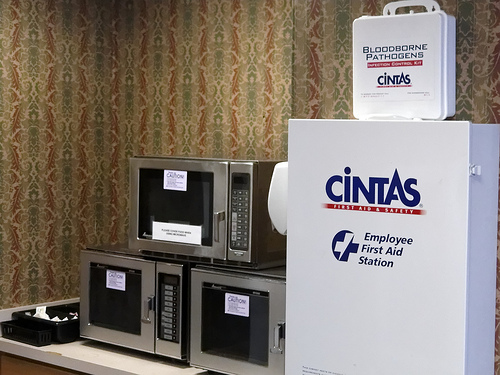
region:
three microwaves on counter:
[73, 150, 291, 373]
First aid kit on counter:
[290, 114, 490, 373]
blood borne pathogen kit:
[343, 3, 459, 119]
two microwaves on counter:
[83, 243, 290, 373]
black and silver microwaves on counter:
[75, 154, 282, 374]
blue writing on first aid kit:
[327, 164, 426, 207]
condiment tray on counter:
[12, 299, 93, 342]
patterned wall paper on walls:
[4, 7, 134, 287]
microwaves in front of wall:
[82, 149, 281, 371]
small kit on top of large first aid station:
[353, 3, 448, 128]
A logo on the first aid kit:
[318, 168, 425, 276]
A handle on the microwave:
[138, 291, 153, 322]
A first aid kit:
[281, 111, 491, 371]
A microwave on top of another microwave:
[131, 153, 269, 265]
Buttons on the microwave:
[228, 171, 250, 251]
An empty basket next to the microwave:
[6, 320, 48, 344]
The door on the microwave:
[131, 157, 222, 254]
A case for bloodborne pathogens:
[353, 8, 452, 117]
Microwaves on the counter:
[80, 155, 282, 373]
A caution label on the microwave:
[162, 171, 187, 193]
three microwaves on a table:
[12, 80, 384, 374]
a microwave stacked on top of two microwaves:
[57, 130, 365, 371]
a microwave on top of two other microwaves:
[28, 103, 347, 371]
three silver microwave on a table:
[55, 115, 347, 372]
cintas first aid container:
[265, 11, 497, 293]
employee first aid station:
[257, 118, 499, 368]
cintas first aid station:
[229, 73, 498, 345]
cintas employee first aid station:
[221, 77, 492, 344]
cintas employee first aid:
[265, 66, 497, 361]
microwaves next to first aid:
[57, 73, 439, 369]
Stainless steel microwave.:
[124, 152, 267, 267]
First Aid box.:
[288, 118, 495, 373]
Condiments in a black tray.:
[12, 303, 78, 341]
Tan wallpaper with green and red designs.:
[3, 0, 277, 152]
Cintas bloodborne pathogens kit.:
[349, 2, 459, 122]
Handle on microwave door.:
[264, 318, 287, 360]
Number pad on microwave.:
[228, 186, 248, 251]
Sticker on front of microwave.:
[160, 168, 190, 193]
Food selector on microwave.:
[158, 284, 178, 344]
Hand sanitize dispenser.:
[267, 159, 289, 235]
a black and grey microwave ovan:
[128, 149, 271, 261]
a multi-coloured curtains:
[100, 35, 302, 113]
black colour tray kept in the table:
[16, 295, 80, 345]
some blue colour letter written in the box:
[336, 213, 413, 278]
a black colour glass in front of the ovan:
[201, 283, 268, 365]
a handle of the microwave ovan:
[273, 318, 285, 358]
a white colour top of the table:
[17, 330, 199, 372]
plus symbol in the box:
[332, 227, 359, 262]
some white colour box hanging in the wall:
[339, 3, 464, 108]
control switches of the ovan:
[227, 191, 249, 254]